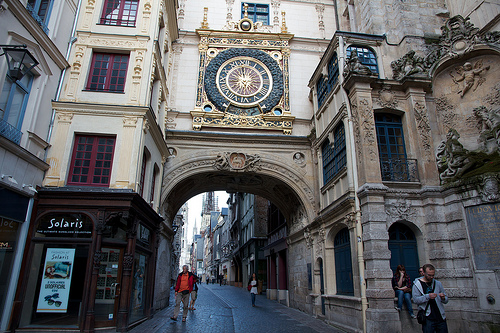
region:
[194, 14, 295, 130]
cock surrounded by gold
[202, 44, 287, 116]
ornate gold and green clock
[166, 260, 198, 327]
man with orange shirt walking under arch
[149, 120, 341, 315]
arch with a walkway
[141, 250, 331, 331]
road passing under an archway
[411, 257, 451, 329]
man in gray sweater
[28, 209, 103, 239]
white lettering saying Solaris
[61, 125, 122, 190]
red framed window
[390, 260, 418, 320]
woman leaning against building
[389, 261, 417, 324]
woman wearing jeans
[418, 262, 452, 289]
Man has short hair.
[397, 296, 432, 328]
Black bag around man's shoulder.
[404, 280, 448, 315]
Man wearing gray hoodie.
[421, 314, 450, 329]
Man wearing blue jeans.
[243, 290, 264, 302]
Person wearing blue jeans.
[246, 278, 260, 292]
Person wearing white shirt.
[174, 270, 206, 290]
Person wearing red and black coat.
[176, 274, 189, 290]
Person wearing orange shirt.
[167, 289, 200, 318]
Person wearing khaki pants.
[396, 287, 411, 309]
Person wearing blue jeans.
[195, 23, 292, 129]
ornate face of a clock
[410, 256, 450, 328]
man in a grey jacket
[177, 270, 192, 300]
man in an orange shirt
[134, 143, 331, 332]
ornate archway on a building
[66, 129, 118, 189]
red painted window panes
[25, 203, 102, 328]
advertisement on a store front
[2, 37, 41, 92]
turned off street light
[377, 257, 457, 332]
group of people on the street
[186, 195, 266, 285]
buildings seen through an archway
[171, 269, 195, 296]
red jacket on a man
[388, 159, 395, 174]
part of a wall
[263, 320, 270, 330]
part of a street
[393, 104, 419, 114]
part of a window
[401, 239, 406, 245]
part of a door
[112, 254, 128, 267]
edge of a window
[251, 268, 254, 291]
part of an arm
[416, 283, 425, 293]
part of a shirt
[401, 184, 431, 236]
edge of a window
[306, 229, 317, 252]
part of a wall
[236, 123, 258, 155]
part of a clock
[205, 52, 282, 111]
black clock face with gold roman numerals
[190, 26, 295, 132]
elaborate gold frame around a black clock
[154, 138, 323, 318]
elaborate archway leading under a building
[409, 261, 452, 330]
man wearing black pants and a light blue sweatshirt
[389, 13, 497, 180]
elbaorate design in the side of a building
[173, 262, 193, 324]
man walking with tan pants and an orange jacket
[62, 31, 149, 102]
elaborate cement work around a window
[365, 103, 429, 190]
window with an iron gate across the bottom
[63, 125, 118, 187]
window with red framing around the panes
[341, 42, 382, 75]
arched window with many panes of glass